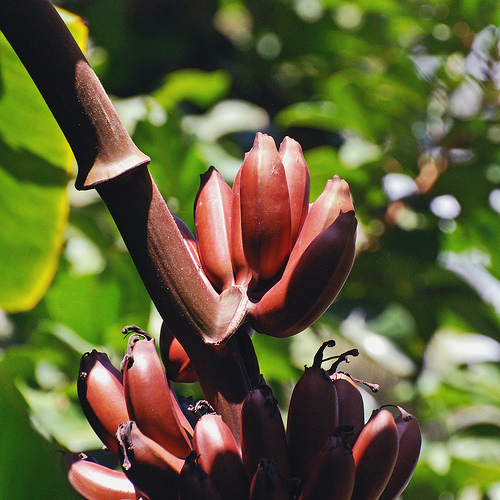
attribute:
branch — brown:
[1, 0, 263, 455]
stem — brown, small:
[120, 317, 153, 349]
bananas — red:
[156, 179, 436, 366]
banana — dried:
[105, 333, 210, 453]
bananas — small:
[121, 366, 416, 494]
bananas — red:
[61, 130, 420, 498]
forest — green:
[0, 3, 498, 498]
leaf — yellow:
[2, 10, 103, 327]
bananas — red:
[171, 125, 358, 357]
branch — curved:
[160, 247, 257, 351]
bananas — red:
[74, 93, 379, 333]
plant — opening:
[53, 325, 239, 497]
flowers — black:
[315, 338, 335, 368]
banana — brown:
[118, 322, 194, 459]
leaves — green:
[251, 43, 498, 195]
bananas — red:
[173, 119, 359, 340]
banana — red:
[254, 207, 374, 341]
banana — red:
[120, 334, 190, 466]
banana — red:
[235, 130, 291, 280]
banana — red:
[194, 167, 234, 288]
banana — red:
[78, 354, 119, 450]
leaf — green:
[2, 3, 91, 315]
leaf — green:
[135, 66, 225, 232]